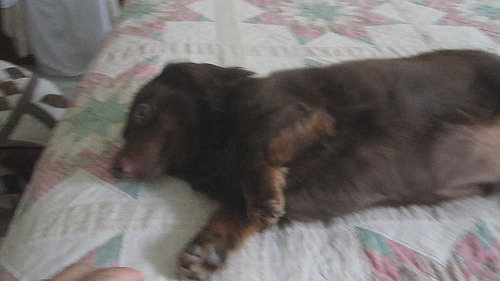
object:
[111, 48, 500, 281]
dog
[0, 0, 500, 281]
quilt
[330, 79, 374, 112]
brown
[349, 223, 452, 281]
colored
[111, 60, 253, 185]
head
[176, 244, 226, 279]
paw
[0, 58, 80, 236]
floor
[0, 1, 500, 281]
bed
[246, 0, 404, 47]
star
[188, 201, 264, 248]
legs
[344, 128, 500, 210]
belly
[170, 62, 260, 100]
ear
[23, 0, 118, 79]
dress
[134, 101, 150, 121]
eye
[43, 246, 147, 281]
hand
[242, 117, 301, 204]
leg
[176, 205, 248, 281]
right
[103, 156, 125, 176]
nose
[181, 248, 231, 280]
bottom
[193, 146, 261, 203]
chest